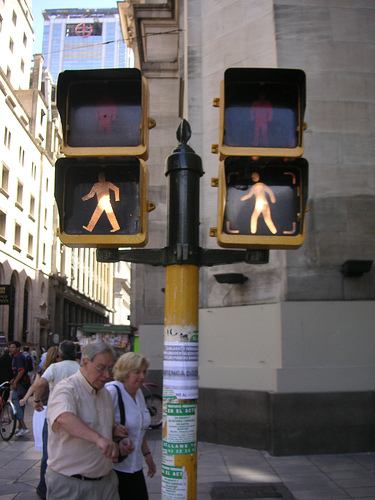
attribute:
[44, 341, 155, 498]
people — lunch hour, walking around slowly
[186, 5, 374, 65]
building — light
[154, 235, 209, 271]
clamp — black 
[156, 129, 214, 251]
metal pole — yellow color metal 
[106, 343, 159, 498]
woman — walking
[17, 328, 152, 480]
people — out 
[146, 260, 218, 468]
pole — yellow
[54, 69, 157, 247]
sign — yellow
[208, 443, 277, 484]
city sidewalk —  city 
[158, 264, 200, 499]
pole — yellow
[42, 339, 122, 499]
man — walking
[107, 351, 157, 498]
woman — black 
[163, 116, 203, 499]
pole — metal 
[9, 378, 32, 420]
shorts —  blue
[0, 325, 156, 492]
business — own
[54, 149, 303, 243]
signal — walk 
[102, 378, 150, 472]
shirt — white